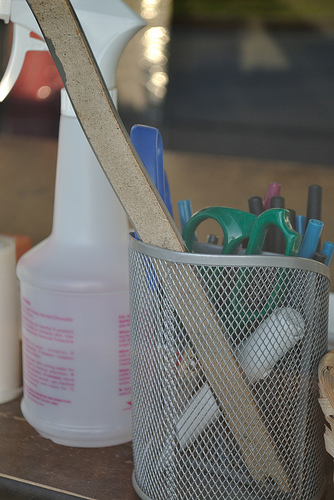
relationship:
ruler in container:
[39, 39, 249, 386] [164, 247, 301, 449]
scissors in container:
[133, 127, 177, 188] [164, 247, 301, 449]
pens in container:
[184, 176, 326, 338] [164, 247, 301, 449]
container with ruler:
[164, 247, 301, 449] [39, 39, 249, 386]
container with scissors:
[164, 247, 301, 449] [133, 127, 177, 188]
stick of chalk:
[238, 316, 300, 371] [231, 293, 330, 399]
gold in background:
[135, 44, 199, 101] [167, 44, 333, 124]